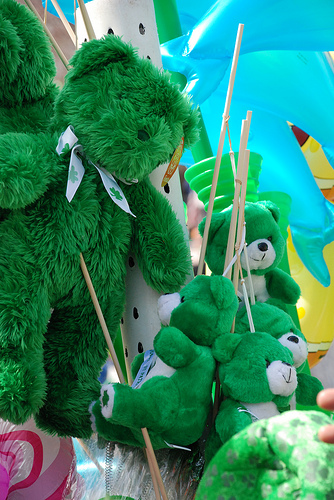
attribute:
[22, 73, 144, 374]
bear — fluffy, green, large, stuffed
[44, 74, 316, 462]
toys — grouped, green, displayed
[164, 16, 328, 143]
toys — blue, large, blown up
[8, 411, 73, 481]
balloon — printed, inflated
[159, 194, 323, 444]
bears — grouped, green, fluffy, identical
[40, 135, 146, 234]
ribbon — white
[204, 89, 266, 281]
sticks — large, wooden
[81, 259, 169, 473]
stick — wooden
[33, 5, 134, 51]
container — plastci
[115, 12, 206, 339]
pole — white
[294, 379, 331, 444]
fingers — present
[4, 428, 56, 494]
circle — red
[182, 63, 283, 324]
sticks — tan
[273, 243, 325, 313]
toy — yellow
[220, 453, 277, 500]
spot — green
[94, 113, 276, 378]
animals — plush, stuffed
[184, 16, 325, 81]
whale — blue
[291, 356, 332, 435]
fingertips — present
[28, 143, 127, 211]
bow — blue, white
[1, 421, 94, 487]
ballon — pink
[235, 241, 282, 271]
snout — white